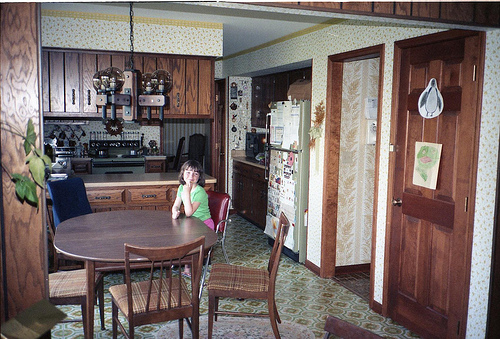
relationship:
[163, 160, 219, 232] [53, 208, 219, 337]
girl sitting at table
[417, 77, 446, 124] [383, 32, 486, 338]
drawing on door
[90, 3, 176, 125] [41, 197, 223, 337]
light fixture hanging over table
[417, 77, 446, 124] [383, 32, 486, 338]
drawing hanging on door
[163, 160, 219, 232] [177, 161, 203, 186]
girl has head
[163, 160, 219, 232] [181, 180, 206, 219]
girl has left arm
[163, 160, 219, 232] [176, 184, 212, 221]
girl wearing top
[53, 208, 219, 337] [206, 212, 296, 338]
table has chair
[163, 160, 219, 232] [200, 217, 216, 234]
girl wearing shorts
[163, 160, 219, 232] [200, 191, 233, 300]
girl sitting in chair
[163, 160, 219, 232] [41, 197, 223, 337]
girl sitting table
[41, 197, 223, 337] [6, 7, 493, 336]
table in kitchen